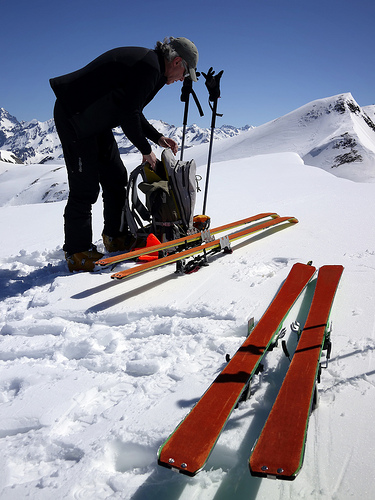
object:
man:
[50, 36, 197, 273]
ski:
[246, 264, 345, 480]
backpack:
[125, 146, 197, 248]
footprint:
[116, 350, 163, 375]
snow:
[0, 93, 373, 499]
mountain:
[0, 107, 261, 169]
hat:
[163, 28, 200, 82]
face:
[165, 52, 192, 85]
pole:
[197, 96, 220, 216]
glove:
[201, 64, 227, 101]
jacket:
[49, 45, 167, 154]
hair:
[160, 36, 178, 64]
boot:
[64, 242, 104, 276]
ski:
[95, 215, 300, 283]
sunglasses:
[179, 63, 192, 78]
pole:
[176, 94, 190, 161]